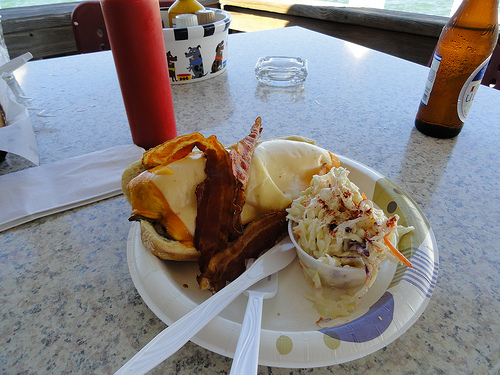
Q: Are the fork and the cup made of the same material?
A: Yes, both the fork and the cup are made of plastic.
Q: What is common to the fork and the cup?
A: The material, both the fork and the cup are plastic.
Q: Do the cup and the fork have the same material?
A: Yes, both the cup and the fork are made of plastic.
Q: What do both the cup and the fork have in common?
A: The material, both the cup and the fork are plastic.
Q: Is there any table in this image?
A: Yes, there is a table.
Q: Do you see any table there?
A: Yes, there is a table.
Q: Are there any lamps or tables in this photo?
A: Yes, there is a table.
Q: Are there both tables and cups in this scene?
A: Yes, there are both a table and a cup.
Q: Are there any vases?
A: No, there are no vases.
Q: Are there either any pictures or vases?
A: No, there are no vases or pictures.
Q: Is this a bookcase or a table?
A: This is a table.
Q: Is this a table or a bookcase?
A: This is a table.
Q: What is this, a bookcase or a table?
A: This is a table.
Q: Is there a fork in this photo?
A: Yes, there is a fork.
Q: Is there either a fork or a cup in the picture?
A: Yes, there is a fork.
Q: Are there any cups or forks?
A: Yes, there is a fork.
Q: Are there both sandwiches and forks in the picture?
A: Yes, there are both a fork and a sandwich.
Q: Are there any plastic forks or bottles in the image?
A: Yes, there is a plastic fork.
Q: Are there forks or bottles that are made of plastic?
A: Yes, the fork is made of plastic.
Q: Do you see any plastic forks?
A: Yes, there is a fork that is made of plastic.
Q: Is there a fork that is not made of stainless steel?
A: Yes, there is a fork that is made of plastic.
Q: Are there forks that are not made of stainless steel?
A: Yes, there is a fork that is made of plastic.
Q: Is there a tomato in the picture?
A: No, there are no tomatoes.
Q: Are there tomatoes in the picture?
A: No, there are no tomatoes.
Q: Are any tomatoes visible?
A: No, there are no tomatoes.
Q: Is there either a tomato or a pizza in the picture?
A: No, there are no tomatoes or pizzas.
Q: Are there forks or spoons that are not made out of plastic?
A: No, there is a fork but it is made of plastic.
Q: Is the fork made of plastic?
A: Yes, the fork is made of plastic.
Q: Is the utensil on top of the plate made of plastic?
A: Yes, the fork is made of plastic.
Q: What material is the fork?
A: The fork is made of plastic.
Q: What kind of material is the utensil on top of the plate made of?
A: The fork is made of plastic.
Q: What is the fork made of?
A: The fork is made of plastic.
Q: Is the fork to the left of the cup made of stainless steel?
A: No, the fork is made of plastic.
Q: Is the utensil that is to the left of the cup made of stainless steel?
A: No, the fork is made of plastic.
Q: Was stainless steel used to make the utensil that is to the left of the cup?
A: No, the fork is made of plastic.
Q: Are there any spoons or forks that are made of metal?
A: No, there is a fork but it is made of plastic.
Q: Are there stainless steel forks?
A: No, there is a fork but it is made of plastic.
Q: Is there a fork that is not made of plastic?
A: No, there is a fork but it is made of plastic.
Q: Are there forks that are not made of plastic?
A: No, there is a fork but it is made of plastic.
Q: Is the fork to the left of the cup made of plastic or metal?
A: The fork is made of plastic.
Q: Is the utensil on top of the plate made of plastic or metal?
A: The fork is made of plastic.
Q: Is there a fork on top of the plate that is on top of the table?
A: Yes, there is a fork on top of the plate.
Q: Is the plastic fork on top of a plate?
A: Yes, the fork is on top of a plate.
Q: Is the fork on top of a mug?
A: No, the fork is on top of a plate.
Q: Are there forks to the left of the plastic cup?
A: Yes, there is a fork to the left of the cup.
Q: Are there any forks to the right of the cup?
A: No, the fork is to the left of the cup.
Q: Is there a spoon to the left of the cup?
A: No, there is a fork to the left of the cup.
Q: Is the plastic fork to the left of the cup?
A: Yes, the fork is to the left of the cup.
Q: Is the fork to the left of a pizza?
A: No, the fork is to the left of the cup.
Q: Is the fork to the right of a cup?
A: No, the fork is to the left of a cup.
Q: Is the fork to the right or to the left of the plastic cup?
A: The fork is to the left of the cup.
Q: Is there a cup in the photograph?
A: Yes, there is a cup.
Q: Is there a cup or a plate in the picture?
A: Yes, there is a cup.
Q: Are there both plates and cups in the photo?
A: Yes, there are both a cup and plates.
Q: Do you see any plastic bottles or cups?
A: Yes, there is a plastic cup.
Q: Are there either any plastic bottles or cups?
A: Yes, there is a plastic cup.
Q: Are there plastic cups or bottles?
A: Yes, there is a plastic cup.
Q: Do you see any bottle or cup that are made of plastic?
A: Yes, the cup is made of plastic.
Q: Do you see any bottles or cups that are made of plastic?
A: Yes, the cup is made of plastic.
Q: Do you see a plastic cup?
A: Yes, there is a cup that is made of plastic.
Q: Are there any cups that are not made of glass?
A: Yes, there is a cup that is made of plastic.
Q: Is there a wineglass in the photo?
A: No, there are no wine glasses.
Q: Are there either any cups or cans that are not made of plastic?
A: No, there is a cup but it is made of plastic.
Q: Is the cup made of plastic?
A: Yes, the cup is made of plastic.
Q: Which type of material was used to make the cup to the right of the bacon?
A: The cup is made of plastic.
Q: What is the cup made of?
A: The cup is made of plastic.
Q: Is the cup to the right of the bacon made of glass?
A: No, the cup is made of plastic.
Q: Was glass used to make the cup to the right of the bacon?
A: No, the cup is made of plastic.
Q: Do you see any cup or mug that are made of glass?
A: No, there is a cup but it is made of plastic.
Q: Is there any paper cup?
A: No, there is a cup but it is made of plastic.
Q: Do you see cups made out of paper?
A: No, there is a cup but it is made of plastic.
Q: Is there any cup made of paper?
A: No, there is a cup but it is made of plastic.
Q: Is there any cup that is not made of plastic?
A: No, there is a cup but it is made of plastic.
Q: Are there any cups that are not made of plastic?
A: No, there is a cup but it is made of plastic.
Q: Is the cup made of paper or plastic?
A: The cup is made of plastic.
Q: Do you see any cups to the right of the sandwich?
A: Yes, there is a cup to the right of the sandwich.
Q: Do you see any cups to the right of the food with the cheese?
A: Yes, there is a cup to the right of the sandwich.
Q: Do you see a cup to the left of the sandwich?
A: No, the cup is to the right of the sandwich.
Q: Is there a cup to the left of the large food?
A: No, the cup is to the right of the sandwich.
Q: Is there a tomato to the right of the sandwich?
A: No, there is a cup to the right of the sandwich.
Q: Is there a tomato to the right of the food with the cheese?
A: No, there is a cup to the right of the sandwich.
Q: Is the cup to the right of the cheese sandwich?
A: Yes, the cup is to the right of the sandwich.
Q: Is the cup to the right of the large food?
A: Yes, the cup is to the right of the sandwich.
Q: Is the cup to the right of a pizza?
A: No, the cup is to the right of the sandwich.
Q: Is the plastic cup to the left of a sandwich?
A: No, the cup is to the right of a sandwich.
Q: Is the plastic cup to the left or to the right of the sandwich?
A: The cup is to the right of the sandwich.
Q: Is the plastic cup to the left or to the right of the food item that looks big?
A: The cup is to the right of the sandwich.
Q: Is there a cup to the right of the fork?
A: Yes, there is a cup to the right of the fork.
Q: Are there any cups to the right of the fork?
A: Yes, there is a cup to the right of the fork.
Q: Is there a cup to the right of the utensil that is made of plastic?
A: Yes, there is a cup to the right of the fork.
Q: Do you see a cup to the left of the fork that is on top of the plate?
A: No, the cup is to the right of the fork.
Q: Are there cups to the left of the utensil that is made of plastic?
A: No, the cup is to the right of the fork.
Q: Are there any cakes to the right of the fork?
A: No, there is a cup to the right of the fork.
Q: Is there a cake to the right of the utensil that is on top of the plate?
A: No, there is a cup to the right of the fork.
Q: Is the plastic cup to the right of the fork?
A: Yes, the cup is to the right of the fork.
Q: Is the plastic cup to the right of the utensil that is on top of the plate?
A: Yes, the cup is to the right of the fork.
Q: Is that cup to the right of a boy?
A: No, the cup is to the right of the fork.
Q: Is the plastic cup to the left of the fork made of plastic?
A: No, the cup is to the right of the fork.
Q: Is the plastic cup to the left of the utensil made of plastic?
A: No, the cup is to the right of the fork.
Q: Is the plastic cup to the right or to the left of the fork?
A: The cup is to the right of the fork.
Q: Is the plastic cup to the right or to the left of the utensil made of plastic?
A: The cup is to the right of the fork.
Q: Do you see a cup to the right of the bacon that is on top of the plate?
A: Yes, there is a cup to the right of the bacon.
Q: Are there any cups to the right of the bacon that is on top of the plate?
A: Yes, there is a cup to the right of the bacon.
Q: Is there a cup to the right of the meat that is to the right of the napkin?
A: Yes, there is a cup to the right of the bacon.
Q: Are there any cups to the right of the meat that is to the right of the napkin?
A: Yes, there is a cup to the right of the bacon.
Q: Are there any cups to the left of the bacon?
A: No, the cup is to the right of the bacon.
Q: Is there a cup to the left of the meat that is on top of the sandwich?
A: No, the cup is to the right of the bacon.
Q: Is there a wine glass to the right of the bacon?
A: No, there is a cup to the right of the bacon.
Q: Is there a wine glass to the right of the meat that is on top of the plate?
A: No, there is a cup to the right of the bacon.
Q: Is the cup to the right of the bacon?
A: Yes, the cup is to the right of the bacon.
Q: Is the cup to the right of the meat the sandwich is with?
A: Yes, the cup is to the right of the bacon.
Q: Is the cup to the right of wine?
A: No, the cup is to the right of the bacon.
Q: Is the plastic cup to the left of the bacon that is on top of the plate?
A: No, the cup is to the right of the bacon.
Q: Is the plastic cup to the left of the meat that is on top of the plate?
A: No, the cup is to the right of the bacon.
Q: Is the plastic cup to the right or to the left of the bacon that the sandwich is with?
A: The cup is to the right of the bacon.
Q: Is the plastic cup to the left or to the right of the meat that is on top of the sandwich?
A: The cup is to the right of the bacon.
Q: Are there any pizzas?
A: No, there are no pizzas.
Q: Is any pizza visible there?
A: No, there are no pizzas.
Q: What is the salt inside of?
A: The salt is inside the bowl.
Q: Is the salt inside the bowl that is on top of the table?
A: Yes, the salt is inside the bowl.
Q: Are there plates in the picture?
A: Yes, there is a plate.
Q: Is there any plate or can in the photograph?
A: Yes, there is a plate.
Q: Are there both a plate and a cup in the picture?
A: Yes, there are both a plate and a cup.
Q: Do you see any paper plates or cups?
A: Yes, there is a paper plate.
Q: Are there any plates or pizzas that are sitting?
A: Yes, the plate is sitting.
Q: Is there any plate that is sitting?
A: Yes, there is a plate that is sitting.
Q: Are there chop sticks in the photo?
A: No, there are no chop sticks.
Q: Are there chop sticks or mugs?
A: No, there are no chop sticks or mugs.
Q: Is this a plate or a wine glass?
A: This is a plate.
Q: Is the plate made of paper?
A: Yes, the plate is made of paper.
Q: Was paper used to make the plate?
A: Yes, the plate is made of paper.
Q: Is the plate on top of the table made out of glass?
A: No, the plate is made of paper.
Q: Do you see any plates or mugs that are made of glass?
A: No, there is a plate but it is made of paper.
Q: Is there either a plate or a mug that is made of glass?
A: No, there is a plate but it is made of paper.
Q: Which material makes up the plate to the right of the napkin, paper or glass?
A: The plate is made of paper.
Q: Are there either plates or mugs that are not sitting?
A: No, there is a plate but it is sitting.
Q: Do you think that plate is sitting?
A: Yes, the plate is sitting.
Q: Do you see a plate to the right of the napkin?
A: Yes, there is a plate to the right of the napkin.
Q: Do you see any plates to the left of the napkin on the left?
A: No, the plate is to the right of the napkin.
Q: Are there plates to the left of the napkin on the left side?
A: No, the plate is to the right of the napkin.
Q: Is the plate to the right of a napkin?
A: Yes, the plate is to the right of a napkin.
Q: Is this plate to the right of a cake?
A: No, the plate is to the right of a napkin.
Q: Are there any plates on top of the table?
A: Yes, there is a plate on top of the table.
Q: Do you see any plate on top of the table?
A: Yes, there is a plate on top of the table.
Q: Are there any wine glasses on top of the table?
A: No, there is a plate on top of the table.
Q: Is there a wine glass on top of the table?
A: No, there is a plate on top of the table.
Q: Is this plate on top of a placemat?
A: No, the plate is on top of a table.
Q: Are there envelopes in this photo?
A: No, there are no envelopes.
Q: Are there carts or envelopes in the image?
A: No, there are no envelopes or carts.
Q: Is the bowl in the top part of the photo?
A: Yes, the bowl is in the top of the image.